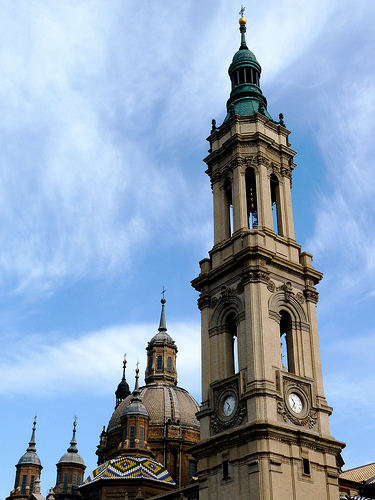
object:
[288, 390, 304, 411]
clock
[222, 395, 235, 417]
clock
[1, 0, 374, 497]
clouds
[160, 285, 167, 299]
cross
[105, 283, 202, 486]
steeple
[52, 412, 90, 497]
steeple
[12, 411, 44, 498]
steeple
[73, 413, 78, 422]
cross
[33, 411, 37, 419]
cross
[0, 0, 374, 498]
sky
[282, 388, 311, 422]
clock face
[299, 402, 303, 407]
roman numerals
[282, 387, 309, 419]
6:55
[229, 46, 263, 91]
green turret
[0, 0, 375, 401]
blue sky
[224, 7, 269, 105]
church roof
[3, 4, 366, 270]
sky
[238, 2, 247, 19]
cross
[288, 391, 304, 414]
10:35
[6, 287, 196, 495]
several steeples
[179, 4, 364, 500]
large cathedral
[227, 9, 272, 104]
cathedral steeple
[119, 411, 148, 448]
copper steeple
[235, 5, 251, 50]
church spires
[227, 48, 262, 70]
dome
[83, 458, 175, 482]
decorative tile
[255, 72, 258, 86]
metal element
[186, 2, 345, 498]
church tower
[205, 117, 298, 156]
stone masonry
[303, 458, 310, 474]
small window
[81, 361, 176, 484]
church steeples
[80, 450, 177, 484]
design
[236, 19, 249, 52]
roof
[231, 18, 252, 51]
top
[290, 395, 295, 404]
clock hands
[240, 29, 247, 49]
pillars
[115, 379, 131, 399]
roof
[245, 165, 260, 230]
archway